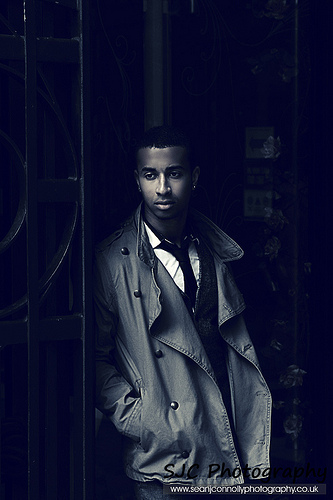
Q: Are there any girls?
A: No, there are no girls.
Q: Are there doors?
A: Yes, there is a door.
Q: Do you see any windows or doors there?
A: Yes, there is a door.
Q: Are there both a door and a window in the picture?
A: No, there is a door but no windows.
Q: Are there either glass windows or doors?
A: Yes, there is a glass door.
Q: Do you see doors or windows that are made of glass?
A: Yes, the door is made of glass.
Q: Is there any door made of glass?
A: Yes, there is a door that is made of glass.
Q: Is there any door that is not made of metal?
A: Yes, there is a door that is made of glass.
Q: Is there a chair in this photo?
A: No, there are no chairs.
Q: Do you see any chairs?
A: No, there are no chairs.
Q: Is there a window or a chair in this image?
A: No, there are no chairs or windows.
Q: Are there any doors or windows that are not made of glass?
A: No, there is a door but it is made of glass.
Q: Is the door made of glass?
A: Yes, the door is made of glass.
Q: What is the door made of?
A: The door is made of glass.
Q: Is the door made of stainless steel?
A: No, the door is made of glass.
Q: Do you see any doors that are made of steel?
A: No, there is a door but it is made of glass.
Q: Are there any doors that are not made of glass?
A: No, there is a door but it is made of glass.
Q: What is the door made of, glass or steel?
A: The door is made of glass.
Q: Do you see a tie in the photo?
A: Yes, there is a tie.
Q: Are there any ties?
A: Yes, there is a tie.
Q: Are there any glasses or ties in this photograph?
A: Yes, there is a tie.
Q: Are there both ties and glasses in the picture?
A: Yes, there are both a tie and glasses.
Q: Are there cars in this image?
A: No, there are no cars.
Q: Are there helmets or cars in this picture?
A: No, there are no cars or helmets.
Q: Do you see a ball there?
A: No, there are no balls.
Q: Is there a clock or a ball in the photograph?
A: No, there are no balls or clocks.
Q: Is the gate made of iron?
A: Yes, the gate is made of iron.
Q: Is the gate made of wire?
A: No, the gate is made of iron.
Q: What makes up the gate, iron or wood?
A: The gate is made of iron.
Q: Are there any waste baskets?
A: No, there are no waste baskets.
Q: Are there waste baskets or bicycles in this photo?
A: No, there are no waste baskets or bicycles.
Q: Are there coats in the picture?
A: Yes, there is a coat.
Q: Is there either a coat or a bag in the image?
A: Yes, there is a coat.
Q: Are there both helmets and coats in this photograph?
A: No, there is a coat but no helmets.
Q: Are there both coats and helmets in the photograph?
A: No, there is a coat but no helmets.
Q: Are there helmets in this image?
A: No, there are no helmets.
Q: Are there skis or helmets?
A: No, there are no helmets or skis.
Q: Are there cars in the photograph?
A: No, there are no cars.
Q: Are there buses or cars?
A: No, there are no cars or buses.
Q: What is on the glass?
A: The sign is on the glass.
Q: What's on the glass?
A: The sign is on the glass.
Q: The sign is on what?
A: The sign is on the glass.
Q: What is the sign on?
A: The sign is on the glass.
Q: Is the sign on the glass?
A: Yes, the sign is on the glass.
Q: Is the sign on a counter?
A: No, the sign is on the glass.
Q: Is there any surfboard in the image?
A: No, there are no surfboards.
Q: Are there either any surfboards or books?
A: No, there are no surfboards or books.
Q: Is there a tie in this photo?
A: Yes, there is a tie.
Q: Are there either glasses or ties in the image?
A: Yes, there is a tie.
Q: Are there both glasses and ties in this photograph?
A: Yes, there are both a tie and glasses.